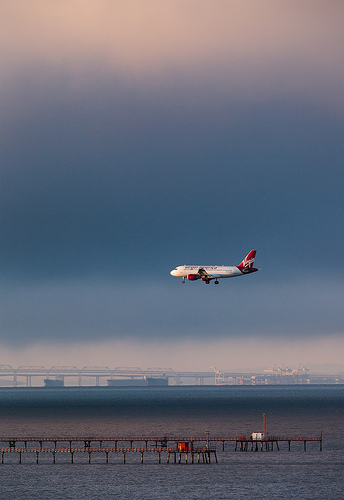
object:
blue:
[14, 153, 114, 275]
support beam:
[317, 440, 321, 451]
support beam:
[303, 440, 307, 455]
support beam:
[287, 440, 291, 454]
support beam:
[275, 442, 281, 453]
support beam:
[233, 441, 237, 453]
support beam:
[165, 450, 169, 465]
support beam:
[140, 450, 144, 466]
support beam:
[105, 452, 109, 464]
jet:
[168, 248, 258, 287]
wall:
[0, 384, 343, 402]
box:
[175, 438, 192, 453]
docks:
[0, 430, 323, 452]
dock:
[0, 445, 218, 464]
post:
[212, 450, 219, 465]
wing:
[237, 248, 256, 270]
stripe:
[242, 255, 257, 267]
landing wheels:
[212, 277, 219, 285]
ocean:
[0, 383, 343, 499]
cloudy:
[0, 0, 343, 372]